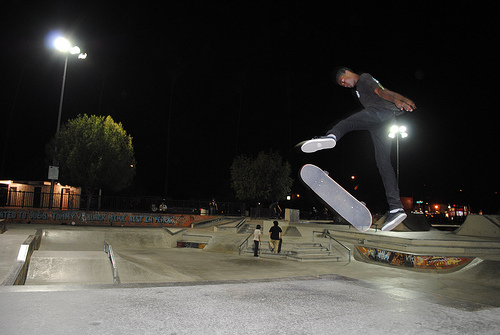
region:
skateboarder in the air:
[282, 58, 427, 243]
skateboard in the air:
[286, 160, 379, 243]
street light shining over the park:
[39, 12, 93, 179]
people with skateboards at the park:
[247, 212, 284, 271]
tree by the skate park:
[47, 120, 129, 199]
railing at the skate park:
[99, 239, 124, 276]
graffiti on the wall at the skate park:
[17, 209, 157, 228]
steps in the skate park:
[284, 235, 342, 265]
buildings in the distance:
[411, 190, 456, 217]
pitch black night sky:
[202, 17, 292, 57]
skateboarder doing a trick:
[296, 65, 421, 235]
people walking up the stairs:
[252, 217, 282, 259]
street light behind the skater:
[385, 117, 410, 140]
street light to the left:
[41, 28, 88, 63]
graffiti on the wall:
[0, 205, 187, 225]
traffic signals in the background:
[398, 190, 478, 219]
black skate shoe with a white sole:
[379, 207, 405, 235]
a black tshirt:
[349, 70, 401, 117]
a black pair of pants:
[320, 100, 409, 207]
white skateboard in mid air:
[301, 162, 374, 233]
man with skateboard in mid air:
[301, 67, 416, 230]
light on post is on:
[69, 43, 80, 54]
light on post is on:
[52, 35, 67, 50]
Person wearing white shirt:
[250, 222, 260, 255]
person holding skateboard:
[268, 220, 283, 252]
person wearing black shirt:
[268, 217, 281, 250]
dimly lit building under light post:
[0, 166, 83, 211]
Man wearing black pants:
[302, 67, 413, 233]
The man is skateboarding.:
[297, 67, 419, 232]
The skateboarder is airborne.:
[296, 65, 418, 232]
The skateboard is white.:
[300, 163, 373, 233]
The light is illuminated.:
[47, 33, 88, 60]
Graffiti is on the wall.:
[0, 210, 175, 224]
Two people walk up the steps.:
[249, 218, 281, 258]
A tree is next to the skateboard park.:
[55, 115, 134, 210]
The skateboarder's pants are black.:
[331, 108, 403, 205]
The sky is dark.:
[130, 0, 499, 56]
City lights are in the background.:
[402, 198, 467, 217]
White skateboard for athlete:
[298, 160, 373, 232]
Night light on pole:
[44, 30, 83, 132]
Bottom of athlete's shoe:
[300, 137, 338, 154]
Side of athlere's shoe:
[375, 209, 410, 231]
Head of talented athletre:
[332, 66, 354, 91]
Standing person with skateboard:
[266, 218, 283, 255]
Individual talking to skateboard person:
[251, 221, 266, 261]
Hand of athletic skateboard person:
[393, 93, 419, 118]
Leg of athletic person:
[369, 130, 404, 211]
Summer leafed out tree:
[58, 117, 132, 212]